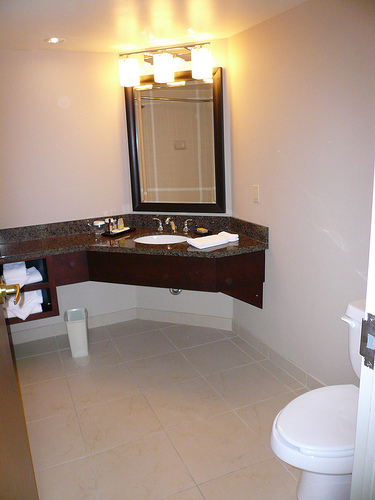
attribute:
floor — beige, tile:
[11, 318, 327, 454]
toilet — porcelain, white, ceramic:
[265, 299, 373, 492]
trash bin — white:
[63, 307, 97, 362]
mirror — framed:
[117, 68, 233, 216]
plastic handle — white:
[338, 308, 356, 329]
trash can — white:
[63, 307, 93, 359]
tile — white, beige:
[126, 349, 238, 424]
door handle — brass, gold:
[1, 279, 22, 307]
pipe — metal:
[168, 287, 183, 297]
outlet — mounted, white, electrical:
[252, 181, 259, 208]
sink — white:
[133, 212, 193, 247]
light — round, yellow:
[115, 40, 213, 86]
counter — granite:
[2, 212, 269, 332]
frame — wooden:
[114, 65, 228, 213]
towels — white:
[191, 229, 236, 250]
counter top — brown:
[2, 227, 267, 263]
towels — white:
[1, 259, 51, 321]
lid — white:
[277, 384, 357, 459]